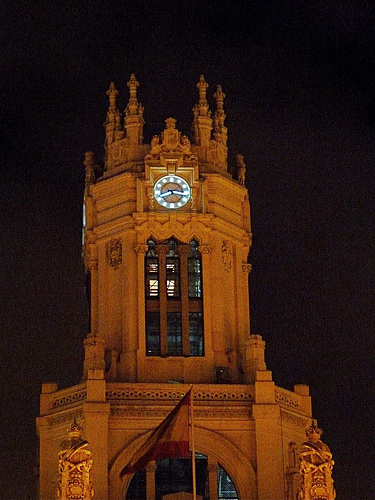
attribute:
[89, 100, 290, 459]
wall — orange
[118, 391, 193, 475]
flag — red, yellow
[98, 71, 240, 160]
structures — crown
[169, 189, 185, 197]
hand — small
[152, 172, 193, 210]
clock face — illuminated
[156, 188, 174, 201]
hand — large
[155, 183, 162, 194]
9 — number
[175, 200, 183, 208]
5 — number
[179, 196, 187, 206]
number — 4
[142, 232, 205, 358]
window — beautiful, black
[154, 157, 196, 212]
clock — lighted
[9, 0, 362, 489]
sky — night, empty